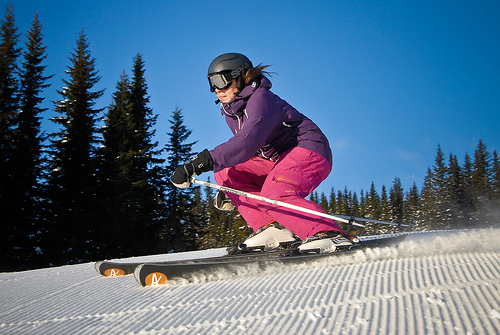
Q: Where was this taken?
A: On a mountain.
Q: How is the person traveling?
A: Snow Skiing.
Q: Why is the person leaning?
A: To help turn.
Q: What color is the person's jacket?
A: Purple.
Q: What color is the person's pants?
A: Pink.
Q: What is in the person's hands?
A: Ski poles.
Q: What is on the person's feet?
A: Snowskies.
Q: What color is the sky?
A: Blue.